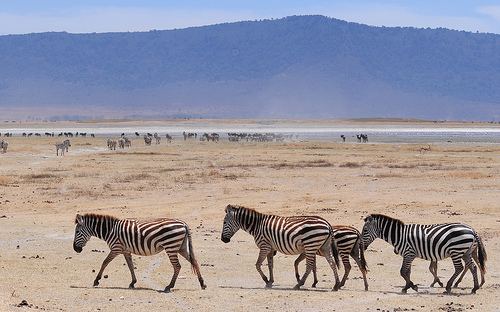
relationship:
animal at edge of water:
[133, 132, 140, 136] [0, 124, 499, 142]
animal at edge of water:
[1, 127, 20, 137] [0, 124, 499, 142]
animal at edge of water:
[226, 132, 241, 144] [0, 124, 499, 142]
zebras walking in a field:
[53, 184, 490, 298] [68, 160, 461, 293]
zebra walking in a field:
[46, 189, 175, 271] [68, 160, 461, 293]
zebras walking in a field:
[220, 204, 343, 291] [68, 160, 461, 293]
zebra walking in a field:
[360, 200, 481, 290] [68, 160, 461, 293]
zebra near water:
[53, 137, 74, 156] [70, 83, 480, 166]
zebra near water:
[105, 137, 115, 147] [70, 83, 480, 166]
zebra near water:
[118, 139, 127, 148] [70, 83, 480, 166]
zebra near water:
[72, 212, 207, 293] [70, 83, 480, 166]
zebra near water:
[163, 133, 173, 143] [70, 83, 480, 166]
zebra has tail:
[72, 212, 207, 293] [182, 223, 200, 274]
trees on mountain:
[5, 34, 497, 86] [0, 15, 499, 107]